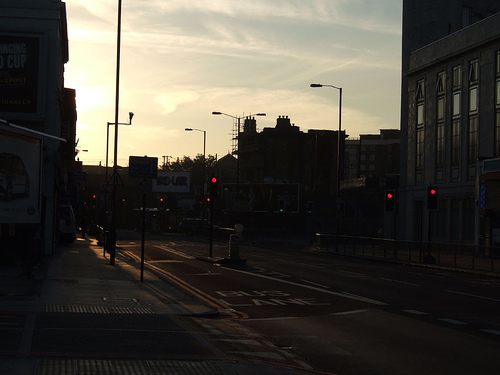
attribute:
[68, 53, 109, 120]
sun setting — bright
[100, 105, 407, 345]
tall street — off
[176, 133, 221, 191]
leaves — green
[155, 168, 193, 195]
sign — large, white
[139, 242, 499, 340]
lines — white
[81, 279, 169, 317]
manhole — closed, square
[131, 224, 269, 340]
lines — yellow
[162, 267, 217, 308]
line — yellow, long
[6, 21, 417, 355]
scene — city, night, empty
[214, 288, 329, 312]
writing — white 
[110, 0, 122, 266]
pole — black, metal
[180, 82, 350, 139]
lights — tall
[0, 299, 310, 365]
driveway — paved, long